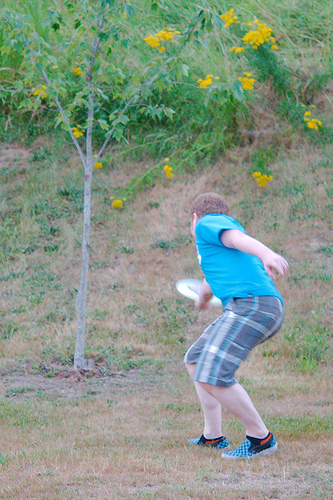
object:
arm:
[197, 259, 212, 303]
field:
[0, 0, 333, 498]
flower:
[69, 65, 81, 80]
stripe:
[260, 434, 273, 446]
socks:
[197, 433, 224, 446]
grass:
[283, 310, 329, 375]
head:
[188, 192, 230, 241]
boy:
[182, 191, 289, 462]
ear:
[193, 210, 199, 226]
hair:
[189, 191, 230, 222]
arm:
[198, 214, 267, 264]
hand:
[256, 247, 291, 282]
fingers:
[270, 264, 286, 283]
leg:
[197, 309, 269, 438]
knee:
[193, 358, 218, 392]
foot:
[221, 428, 279, 462]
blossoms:
[141, 23, 183, 58]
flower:
[196, 69, 218, 91]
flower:
[300, 107, 323, 132]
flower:
[249, 164, 273, 189]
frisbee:
[174, 272, 223, 311]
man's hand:
[193, 290, 209, 318]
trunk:
[74, 75, 101, 376]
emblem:
[194, 247, 206, 269]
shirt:
[193, 212, 285, 306]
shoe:
[185, 433, 228, 448]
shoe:
[221, 428, 278, 463]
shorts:
[181, 296, 285, 386]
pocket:
[224, 290, 250, 327]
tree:
[0, 0, 277, 369]